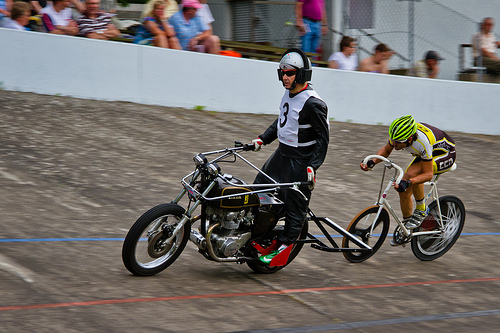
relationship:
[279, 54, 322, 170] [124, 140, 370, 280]
rider on motorbike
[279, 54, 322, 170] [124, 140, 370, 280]
rider riding motorbike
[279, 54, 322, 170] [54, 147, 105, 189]
rider on ground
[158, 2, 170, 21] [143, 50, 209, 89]
person in stand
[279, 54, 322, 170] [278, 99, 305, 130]
rider wearing bib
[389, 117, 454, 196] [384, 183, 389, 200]
rider on bike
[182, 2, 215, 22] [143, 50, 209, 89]
person in stand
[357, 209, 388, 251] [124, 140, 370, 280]
tire on motorbike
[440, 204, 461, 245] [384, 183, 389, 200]
tire on bike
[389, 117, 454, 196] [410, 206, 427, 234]
rider wearing shoes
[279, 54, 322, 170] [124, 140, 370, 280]
rider riding h motorbike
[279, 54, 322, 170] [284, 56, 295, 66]
rider with helmet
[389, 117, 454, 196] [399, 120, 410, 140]
rider with helmet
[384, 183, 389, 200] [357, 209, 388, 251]
bike has tire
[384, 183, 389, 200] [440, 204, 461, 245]
bike has tire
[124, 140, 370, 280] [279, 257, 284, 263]
motorbike with stirrup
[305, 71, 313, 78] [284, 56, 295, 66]
headphones on helmet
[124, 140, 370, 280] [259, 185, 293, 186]
motorbike has handlebar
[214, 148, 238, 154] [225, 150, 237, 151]
motorbike has handlebar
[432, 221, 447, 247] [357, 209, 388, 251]
spokes in tire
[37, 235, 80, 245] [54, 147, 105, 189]
line on ground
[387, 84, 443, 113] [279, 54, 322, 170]
barrier behind rider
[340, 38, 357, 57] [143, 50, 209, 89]
person in stand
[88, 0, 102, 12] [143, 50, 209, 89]
person in stand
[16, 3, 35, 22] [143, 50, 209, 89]
person in stand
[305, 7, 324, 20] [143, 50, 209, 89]
person in stand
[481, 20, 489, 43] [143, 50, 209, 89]
person in stand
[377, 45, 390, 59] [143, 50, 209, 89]
person in stand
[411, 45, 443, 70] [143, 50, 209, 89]
person in stand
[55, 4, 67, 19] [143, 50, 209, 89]
person in stand